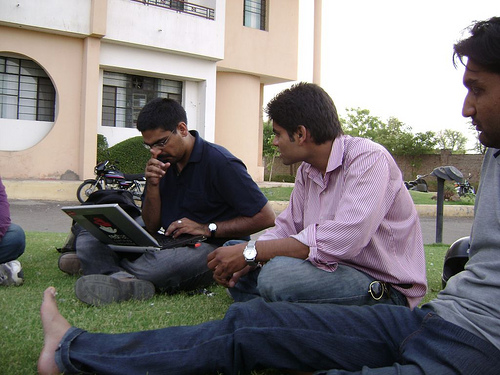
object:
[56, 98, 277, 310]
man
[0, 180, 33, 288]
person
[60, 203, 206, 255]
laptop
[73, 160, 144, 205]
motor bike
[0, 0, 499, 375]
background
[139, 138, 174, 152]
sunglasses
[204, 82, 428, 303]
man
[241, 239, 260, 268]
watch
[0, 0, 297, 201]
building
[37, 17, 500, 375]
people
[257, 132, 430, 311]
shirt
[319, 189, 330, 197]
button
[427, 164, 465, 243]
light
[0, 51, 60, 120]
window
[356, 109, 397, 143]
leaves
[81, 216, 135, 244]
sticker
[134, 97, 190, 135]
hair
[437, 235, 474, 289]
helmet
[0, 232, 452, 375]
grass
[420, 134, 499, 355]
shirt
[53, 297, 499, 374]
pants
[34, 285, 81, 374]
foot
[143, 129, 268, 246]
shirt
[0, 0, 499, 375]
outside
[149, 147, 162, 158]
nose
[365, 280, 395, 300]
sunglasses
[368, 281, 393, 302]
pocket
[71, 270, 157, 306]
shoe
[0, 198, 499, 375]
ground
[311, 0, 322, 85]
pole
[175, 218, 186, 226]
ring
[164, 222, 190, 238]
finger